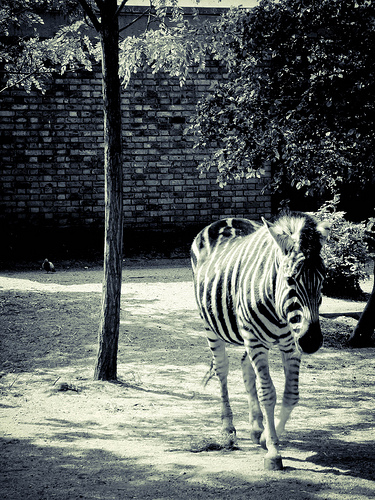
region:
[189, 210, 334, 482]
zebra standing in the forest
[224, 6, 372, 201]
trees with branches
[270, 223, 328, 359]
head of the horse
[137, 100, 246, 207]
bricks in the wall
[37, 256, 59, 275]
bird standing in the dirt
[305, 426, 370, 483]
shadow of the horse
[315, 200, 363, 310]
plants and leaves in the dirt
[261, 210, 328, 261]
ears of the horse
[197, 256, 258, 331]
black and white color lines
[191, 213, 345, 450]
the zebra is walking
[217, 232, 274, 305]
the zebra has black stripes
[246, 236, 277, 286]
the zebra has white stripes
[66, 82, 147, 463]
the tree is skinny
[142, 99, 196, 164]
the wall is brick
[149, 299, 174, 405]
the sun is shining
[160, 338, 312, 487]
the zebra has four legs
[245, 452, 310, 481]
the zebra has hoofs.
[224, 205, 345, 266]
the zebra has two ears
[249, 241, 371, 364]
the zebra is looking at something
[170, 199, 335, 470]
a zebra inside a pen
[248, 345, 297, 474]
front legs of zebra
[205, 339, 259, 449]
back legs of zebra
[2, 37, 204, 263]
a wall of brick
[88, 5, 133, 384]
the trunk of a tree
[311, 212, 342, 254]
right ear of zebra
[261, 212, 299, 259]
left ear of zebra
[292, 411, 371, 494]
shadow cast on the ground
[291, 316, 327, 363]
muzzle of zebra is black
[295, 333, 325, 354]
nostrils of zebra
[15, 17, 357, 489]
black and white photo of an animal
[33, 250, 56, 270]
pigeon on the ground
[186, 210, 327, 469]
zebra making its way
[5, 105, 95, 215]
brick wall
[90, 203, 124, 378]
thin trunk of a tree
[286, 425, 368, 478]
shadow of the animal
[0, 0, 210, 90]
leaves and branches of a tree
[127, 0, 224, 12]
top ledge of the brick wall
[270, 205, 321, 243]
zebra's mane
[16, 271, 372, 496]
dirt field where zebra roams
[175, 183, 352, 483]
Zebra in the zoo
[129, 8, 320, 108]
leaves on a tree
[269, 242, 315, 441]
Zebra walking through the zoo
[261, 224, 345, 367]
zebra with its head up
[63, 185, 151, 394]
Tree growing in the zoo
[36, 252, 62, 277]
Bird in the zoo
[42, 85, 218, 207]
brick wall in the zoo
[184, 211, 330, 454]
zebra in front of the tree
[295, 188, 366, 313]
Bush in the zoo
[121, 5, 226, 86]
Leaves on a tree